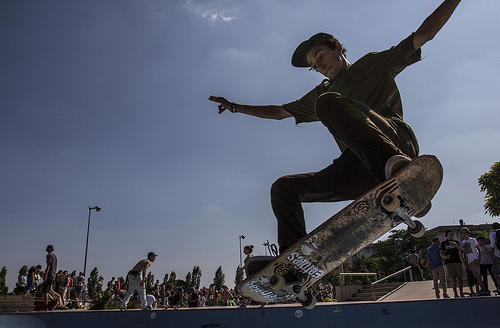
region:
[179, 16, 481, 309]
]a guy performing skate stunts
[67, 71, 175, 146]
a clear blue sky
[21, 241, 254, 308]
people at a skate park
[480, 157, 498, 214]
a tree near the park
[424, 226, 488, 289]
a group of young men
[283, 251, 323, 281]
white letters on a skateboard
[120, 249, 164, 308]
a man not wearing a shirt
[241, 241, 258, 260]
a girl with a bun in her hair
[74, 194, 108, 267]
a street light above the scene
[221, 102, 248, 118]
a watch on a wrist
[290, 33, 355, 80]
A skateboarder's face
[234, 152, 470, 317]
A skateboard being ridden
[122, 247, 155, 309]
A shirtless skater in the background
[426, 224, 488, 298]
A group of three young men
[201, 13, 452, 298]
A guy doing skateboard tricks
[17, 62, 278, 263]
A clear blue sky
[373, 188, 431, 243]
A pair of skateboard wheels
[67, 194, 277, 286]
Light posts near the skate park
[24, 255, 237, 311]
Crowd watching skateboarders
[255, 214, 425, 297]
The skateboard deck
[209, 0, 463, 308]
Man performing a skateboarding stunt in the picture.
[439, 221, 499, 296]
Spectators observing the skateboarder performing a stunt.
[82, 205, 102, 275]
A light pole.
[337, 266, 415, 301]
Steps and support rails.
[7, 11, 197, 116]
Clear sky.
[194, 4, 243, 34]
A small cloud in the sky.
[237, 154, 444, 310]
Skateboard in the air.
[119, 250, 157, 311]
Man on the ground skateboarding.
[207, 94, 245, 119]
Leather bracelet on the man's wrist.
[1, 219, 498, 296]
People at a skate park.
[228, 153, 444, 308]
Tan and black skateboard in midway.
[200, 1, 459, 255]
Boy preforming jump on skateboard.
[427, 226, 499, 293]
Young men watching skateboard performance.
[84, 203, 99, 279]
Light pole behind the crowd.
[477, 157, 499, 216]
Tree top in the landscape.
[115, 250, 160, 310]
Shirtless boy on skateboard.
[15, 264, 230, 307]
Crowd of people watching skateboard performance.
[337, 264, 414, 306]
Concrete steps with metal railings.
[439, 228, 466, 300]
Young man with black shirt.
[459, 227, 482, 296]
Young man with white shirt.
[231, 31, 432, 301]
Boy is skating.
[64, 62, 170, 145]
sky is blue color.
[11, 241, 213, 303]
people are in the side of the ground.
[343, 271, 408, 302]
steps are brown color.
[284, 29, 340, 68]
boy is wearing the cap.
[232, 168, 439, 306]
Skateboard is brown color.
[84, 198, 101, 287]
Lamp post are grey color.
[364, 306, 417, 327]
Ground is grey color.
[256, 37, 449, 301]
Boy is doing tricks in skating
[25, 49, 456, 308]
daytime picture.